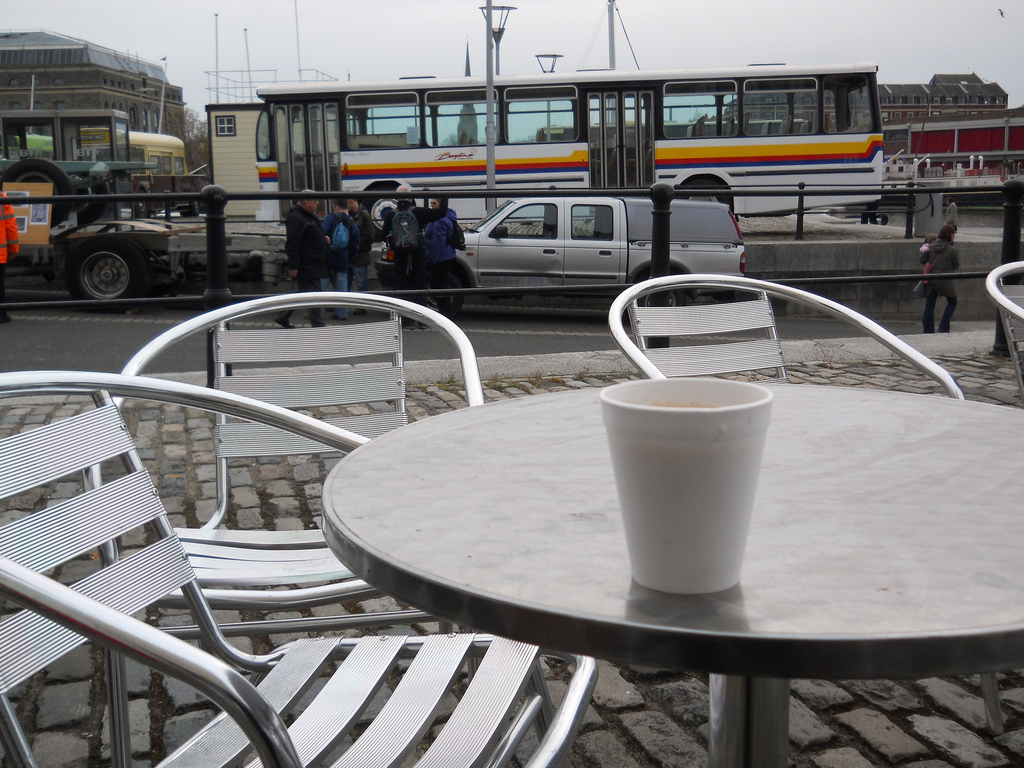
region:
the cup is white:
[601, 377, 775, 596]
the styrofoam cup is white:
[599, 376, 771, 595]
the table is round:
[321, 373, 1017, 766]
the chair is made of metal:
[1, 372, 600, 765]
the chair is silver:
[608, 269, 969, 399]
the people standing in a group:
[288, 180, 467, 332]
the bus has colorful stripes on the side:
[251, 62, 884, 221]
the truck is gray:
[371, 193, 745, 314]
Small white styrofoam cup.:
[588, 375, 788, 606]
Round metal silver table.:
[317, 375, 1022, 767]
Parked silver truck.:
[378, 192, 751, 310]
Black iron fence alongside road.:
[0, 179, 1019, 392]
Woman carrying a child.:
[908, 220, 970, 342]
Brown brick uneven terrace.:
[0, 344, 1022, 766]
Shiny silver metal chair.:
[92, 285, 497, 766]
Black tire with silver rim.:
[73, 244, 141, 309]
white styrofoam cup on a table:
[596, 370, 775, 598]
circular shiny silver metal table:
[317, 377, 1020, 766]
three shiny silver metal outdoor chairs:
[1, 268, 965, 766]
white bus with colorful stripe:
[251, 59, 887, 228]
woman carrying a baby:
[911, 217, 965, 331]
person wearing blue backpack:
[320, 196, 362, 321]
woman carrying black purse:
[415, 189, 467, 316]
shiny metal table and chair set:
[2, 272, 1020, 764]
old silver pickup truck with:
[373, 187, 748, 317]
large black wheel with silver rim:
[54, 233, 150, 311]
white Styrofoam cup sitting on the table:
[584, 373, 782, 607]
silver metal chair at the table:
[112, 335, 351, 624]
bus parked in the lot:
[262, 98, 899, 217]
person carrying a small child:
[912, 218, 976, 323]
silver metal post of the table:
[697, 667, 773, 766]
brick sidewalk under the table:
[805, 701, 977, 759]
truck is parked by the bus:
[451, 181, 734, 303]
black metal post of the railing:
[188, 177, 245, 386]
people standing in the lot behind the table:
[286, 186, 457, 303]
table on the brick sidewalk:
[322, 364, 1021, 639]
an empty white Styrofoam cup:
[599, 378, 774, 584]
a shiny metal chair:
[5, 363, 600, 766]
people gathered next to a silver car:
[288, 181, 745, 333]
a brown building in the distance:
[2, 30, 184, 135]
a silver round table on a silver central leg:
[320, 377, 1022, 767]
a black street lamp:
[482, 2, 511, 72]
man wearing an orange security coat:
[1, 185, 15, 319]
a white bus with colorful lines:
[253, 68, 883, 242]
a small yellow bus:
[80, 128, 183, 176]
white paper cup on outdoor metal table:
[588, 369, 779, 600]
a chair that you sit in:
[11, 352, 590, 765]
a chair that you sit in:
[99, 286, 514, 764]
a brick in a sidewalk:
[626, 700, 709, 765]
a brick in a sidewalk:
[852, 694, 922, 756]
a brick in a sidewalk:
[914, 652, 1004, 723]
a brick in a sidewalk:
[42, 672, 94, 734]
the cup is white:
[617, 380, 748, 622]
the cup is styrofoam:
[602, 370, 773, 609]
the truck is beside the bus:
[438, 96, 743, 270]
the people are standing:
[292, 177, 455, 279]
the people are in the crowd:
[315, 185, 455, 288]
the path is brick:
[125, 383, 676, 519]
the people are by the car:
[354, 175, 788, 311]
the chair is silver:
[117, 298, 491, 615]